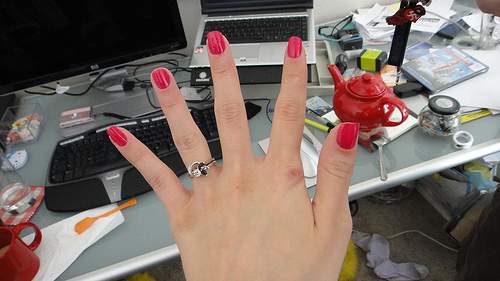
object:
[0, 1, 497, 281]
desk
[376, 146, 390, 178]
small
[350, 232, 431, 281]
sock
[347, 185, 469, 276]
floor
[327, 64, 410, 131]
kettle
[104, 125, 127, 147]
fingernails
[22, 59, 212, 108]
black cords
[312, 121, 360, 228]
finger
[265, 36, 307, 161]
finger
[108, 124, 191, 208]
finger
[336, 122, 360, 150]
nail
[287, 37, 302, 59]
nail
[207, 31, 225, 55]
nail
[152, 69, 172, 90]
nail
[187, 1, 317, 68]
computer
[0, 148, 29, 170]
note pad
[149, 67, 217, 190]
finger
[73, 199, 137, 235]
utensil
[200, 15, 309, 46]
keys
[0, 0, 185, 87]
monitor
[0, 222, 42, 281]
cup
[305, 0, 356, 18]
wall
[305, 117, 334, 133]
pen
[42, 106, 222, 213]
keyboard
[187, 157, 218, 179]
ring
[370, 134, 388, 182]
spoon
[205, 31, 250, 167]
finger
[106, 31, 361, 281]
hand